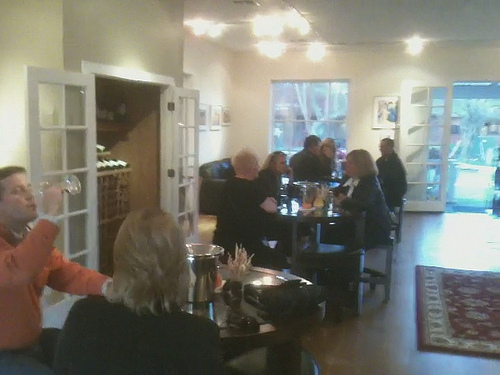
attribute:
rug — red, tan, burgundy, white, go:
[412, 259, 499, 364]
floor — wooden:
[290, 212, 498, 375]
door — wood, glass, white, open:
[397, 78, 450, 213]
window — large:
[268, 76, 345, 150]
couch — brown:
[197, 156, 234, 214]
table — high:
[188, 248, 322, 374]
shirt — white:
[337, 177, 360, 197]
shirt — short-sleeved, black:
[213, 177, 265, 251]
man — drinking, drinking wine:
[1, 161, 111, 374]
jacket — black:
[340, 178, 395, 241]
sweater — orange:
[3, 219, 109, 349]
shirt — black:
[53, 315, 219, 374]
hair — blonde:
[101, 204, 191, 314]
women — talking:
[212, 145, 399, 256]